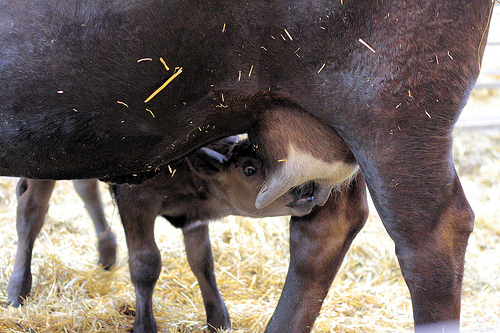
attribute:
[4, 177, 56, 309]
leg — oval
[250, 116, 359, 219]
udder — tan, brown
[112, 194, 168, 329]
leg — bulging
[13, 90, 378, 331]
cow — baby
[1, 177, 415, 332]
hay — in the photo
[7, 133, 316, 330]
baby calf — brown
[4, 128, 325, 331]
calf — baby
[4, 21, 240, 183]
belly — dark, brown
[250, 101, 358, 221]
udders — brown, white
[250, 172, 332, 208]
teats — gray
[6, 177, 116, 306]
legs — back legs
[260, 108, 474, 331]
feet — back feet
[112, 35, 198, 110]
hay — yellow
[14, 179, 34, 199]
opening — dark